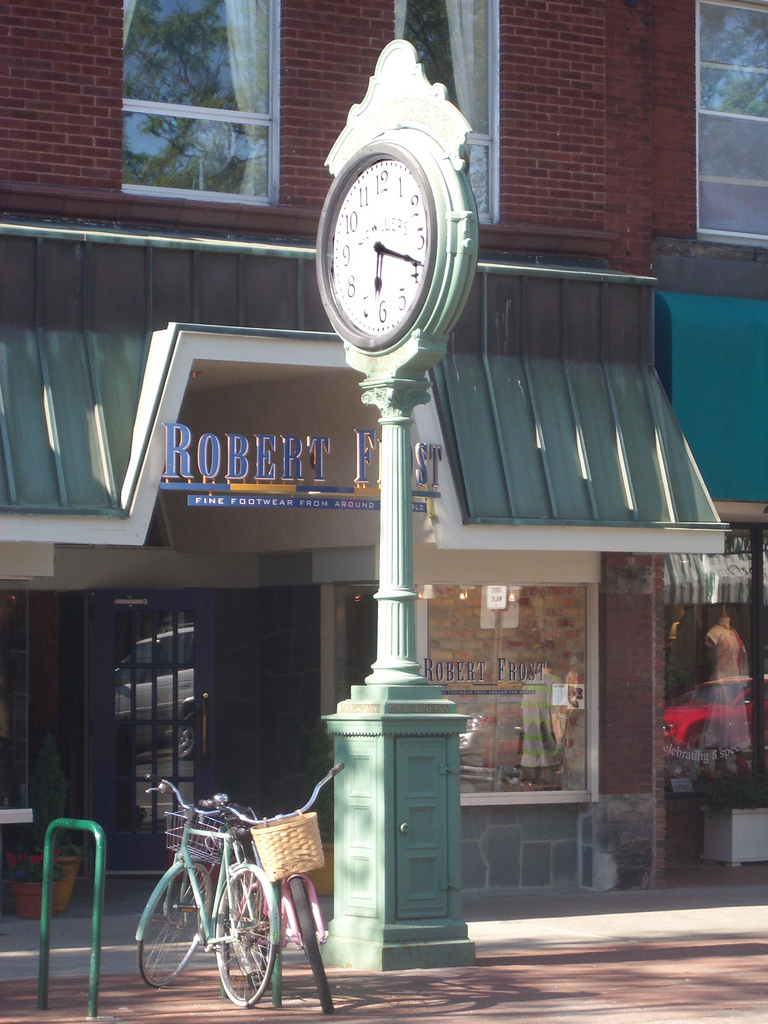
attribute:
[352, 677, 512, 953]
base — green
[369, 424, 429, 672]
pole — sidewalk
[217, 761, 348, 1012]
bike — pink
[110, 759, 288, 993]
bicycle — green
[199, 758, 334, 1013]
bicycle — pink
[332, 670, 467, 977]
base — green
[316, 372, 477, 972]
pole — grey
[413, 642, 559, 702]
lettering — purple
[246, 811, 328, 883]
basket — wicker, brown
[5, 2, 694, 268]
wall — stone, brick, bricks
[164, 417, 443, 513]
sign — purple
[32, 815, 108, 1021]
barrier rail — metal, green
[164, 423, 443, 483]
letters — blue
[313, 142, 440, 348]
clock — white, black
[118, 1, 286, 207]
window — white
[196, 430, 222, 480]
o — blue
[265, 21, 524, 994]
clock — green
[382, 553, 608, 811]
reflections — people